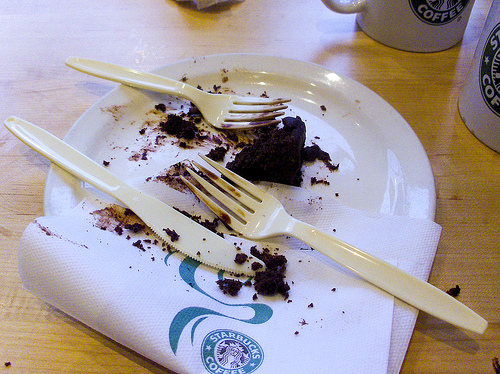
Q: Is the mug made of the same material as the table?
A: No, the mug is made of glass and the table is made of wood.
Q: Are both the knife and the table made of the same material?
A: No, the knife is made of plastic and the table is made of wood.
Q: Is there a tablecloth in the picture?
A: No, there are no tablecloths.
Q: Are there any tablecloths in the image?
A: No, there are no tablecloths.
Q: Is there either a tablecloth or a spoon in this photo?
A: No, there are no tablecloths or spoons.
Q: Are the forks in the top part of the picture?
A: Yes, the forks are in the top of the image.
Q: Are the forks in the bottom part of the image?
A: No, the forks are in the top of the image.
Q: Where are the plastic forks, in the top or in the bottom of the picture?
A: The forks are in the top of the image.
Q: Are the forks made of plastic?
A: Yes, the forks are made of plastic.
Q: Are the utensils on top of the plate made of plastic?
A: Yes, the forks are made of plastic.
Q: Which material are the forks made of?
A: The forks are made of plastic.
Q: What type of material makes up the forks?
A: The forks are made of plastic.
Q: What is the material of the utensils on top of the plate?
A: The forks are made of plastic.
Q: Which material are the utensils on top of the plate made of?
A: The forks are made of plastic.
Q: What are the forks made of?
A: The forks are made of plastic.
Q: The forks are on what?
A: The forks are on the plate.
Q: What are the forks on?
A: The forks are on the plate.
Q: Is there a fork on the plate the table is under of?
A: Yes, there are forks on the plate.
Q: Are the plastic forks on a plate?
A: Yes, the forks are on a plate.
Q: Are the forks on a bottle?
A: No, the forks are on a plate.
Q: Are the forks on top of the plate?
A: Yes, the forks are on top of the plate.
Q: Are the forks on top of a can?
A: No, the forks are on top of the plate.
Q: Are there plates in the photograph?
A: Yes, there is a plate.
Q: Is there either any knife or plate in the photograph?
A: Yes, there is a plate.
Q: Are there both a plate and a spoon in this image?
A: No, there is a plate but no spoons.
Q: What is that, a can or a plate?
A: That is a plate.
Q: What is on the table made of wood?
A: The plate is on the table.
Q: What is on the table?
A: The plate is on the table.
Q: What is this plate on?
A: The plate is on the table.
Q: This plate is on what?
A: The plate is on the table.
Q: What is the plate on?
A: The plate is on the table.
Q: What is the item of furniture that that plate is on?
A: The piece of furniture is a table.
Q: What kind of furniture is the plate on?
A: The plate is on the table.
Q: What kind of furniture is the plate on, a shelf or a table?
A: The plate is on a table.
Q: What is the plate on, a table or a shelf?
A: The plate is on a table.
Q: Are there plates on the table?
A: Yes, there is a plate on the table.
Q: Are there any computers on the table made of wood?
A: No, there is a plate on the table.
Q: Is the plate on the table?
A: Yes, the plate is on the table.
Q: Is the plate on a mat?
A: No, the plate is on the table.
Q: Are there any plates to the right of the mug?
A: No, the plate is to the left of the mug.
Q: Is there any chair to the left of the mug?
A: No, there is a plate to the left of the mug.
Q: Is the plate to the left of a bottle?
A: No, the plate is to the left of a mug.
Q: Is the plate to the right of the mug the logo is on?
A: No, the plate is to the left of the mug.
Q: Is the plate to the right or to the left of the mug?
A: The plate is to the left of the mug.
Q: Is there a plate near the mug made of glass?
A: Yes, there is a plate near the mug.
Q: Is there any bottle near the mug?
A: No, there is a plate near the mug.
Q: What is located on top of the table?
A: The plate is on top of the table.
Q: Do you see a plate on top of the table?
A: Yes, there is a plate on top of the table.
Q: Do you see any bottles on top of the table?
A: No, there is a plate on top of the table.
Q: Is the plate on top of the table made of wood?
A: Yes, the plate is on top of the table.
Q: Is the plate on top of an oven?
A: No, the plate is on top of the table.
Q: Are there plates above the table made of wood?
A: Yes, there is a plate above the table.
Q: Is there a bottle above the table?
A: No, there is a plate above the table.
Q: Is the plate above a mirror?
A: No, the plate is above a table.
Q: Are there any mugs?
A: Yes, there is a mug.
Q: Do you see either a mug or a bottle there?
A: Yes, there is a mug.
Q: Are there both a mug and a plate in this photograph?
A: Yes, there are both a mug and a plate.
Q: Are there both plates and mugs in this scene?
A: Yes, there are both a mug and a plate.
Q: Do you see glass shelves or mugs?
A: Yes, there is a glass mug.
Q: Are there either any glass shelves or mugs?
A: Yes, there is a glass mug.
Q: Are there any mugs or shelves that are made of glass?
A: Yes, the mug is made of glass.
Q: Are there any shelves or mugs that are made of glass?
A: Yes, the mug is made of glass.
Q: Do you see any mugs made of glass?
A: Yes, there is a mug that is made of glass.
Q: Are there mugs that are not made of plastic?
A: Yes, there is a mug that is made of glass.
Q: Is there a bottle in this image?
A: No, there are no bottles.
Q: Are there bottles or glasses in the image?
A: No, there are no bottles or glasses.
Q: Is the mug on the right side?
A: Yes, the mug is on the right of the image.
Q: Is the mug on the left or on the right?
A: The mug is on the right of the image.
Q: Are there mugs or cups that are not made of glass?
A: No, there is a mug but it is made of glass.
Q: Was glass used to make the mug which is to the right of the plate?
A: Yes, the mug is made of glass.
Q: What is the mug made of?
A: The mug is made of glass.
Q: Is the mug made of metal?
A: No, the mug is made of glass.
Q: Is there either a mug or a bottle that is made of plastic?
A: No, there is a mug but it is made of glass.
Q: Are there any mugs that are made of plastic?
A: No, there is a mug but it is made of glass.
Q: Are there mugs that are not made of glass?
A: No, there is a mug but it is made of glass.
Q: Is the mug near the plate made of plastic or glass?
A: The mug is made of glass.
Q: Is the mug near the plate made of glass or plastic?
A: The mug is made of glass.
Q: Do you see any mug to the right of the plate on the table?
A: Yes, there is a mug to the right of the plate.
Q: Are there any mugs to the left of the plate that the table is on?
A: No, the mug is to the right of the plate.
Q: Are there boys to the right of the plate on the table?
A: No, there is a mug to the right of the plate.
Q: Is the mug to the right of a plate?
A: Yes, the mug is to the right of a plate.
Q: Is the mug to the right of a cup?
A: No, the mug is to the right of a plate.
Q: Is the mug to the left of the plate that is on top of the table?
A: No, the mug is to the right of the plate.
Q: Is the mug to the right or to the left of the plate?
A: The mug is to the right of the plate.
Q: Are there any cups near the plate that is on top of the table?
A: No, there is a mug near the plate.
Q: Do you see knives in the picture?
A: Yes, there is a knife.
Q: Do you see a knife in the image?
A: Yes, there is a knife.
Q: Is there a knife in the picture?
A: Yes, there is a knife.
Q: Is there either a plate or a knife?
A: Yes, there is a knife.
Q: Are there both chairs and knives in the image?
A: No, there is a knife but no chairs.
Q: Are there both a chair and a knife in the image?
A: No, there is a knife but no chairs.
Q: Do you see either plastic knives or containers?
A: Yes, there is a plastic knife.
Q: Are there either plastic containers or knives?
A: Yes, there is a plastic knife.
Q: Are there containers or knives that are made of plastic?
A: Yes, the knife is made of plastic.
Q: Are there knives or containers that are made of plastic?
A: Yes, the knife is made of plastic.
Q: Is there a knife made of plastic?
A: Yes, there is a knife that is made of plastic.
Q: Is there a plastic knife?
A: Yes, there is a knife that is made of plastic.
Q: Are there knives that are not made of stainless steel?
A: Yes, there is a knife that is made of plastic.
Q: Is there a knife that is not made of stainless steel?
A: Yes, there is a knife that is made of plastic.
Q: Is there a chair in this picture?
A: No, there are no chairs.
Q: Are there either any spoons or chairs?
A: No, there are no chairs or spoons.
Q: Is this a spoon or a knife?
A: This is a knife.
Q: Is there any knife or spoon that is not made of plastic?
A: No, there is a knife but it is made of plastic.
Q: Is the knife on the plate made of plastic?
A: Yes, the knife is made of plastic.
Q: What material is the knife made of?
A: The knife is made of plastic.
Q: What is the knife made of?
A: The knife is made of plastic.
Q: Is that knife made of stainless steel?
A: No, the knife is made of plastic.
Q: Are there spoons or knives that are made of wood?
A: No, there is a knife but it is made of plastic.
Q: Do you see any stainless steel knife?
A: No, there is a knife but it is made of plastic.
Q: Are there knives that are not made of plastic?
A: No, there is a knife but it is made of plastic.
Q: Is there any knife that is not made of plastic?
A: No, there is a knife but it is made of plastic.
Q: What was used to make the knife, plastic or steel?
A: The knife is made of plastic.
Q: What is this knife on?
A: The knife is on the plate.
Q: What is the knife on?
A: The knife is on the plate.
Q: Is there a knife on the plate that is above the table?
A: Yes, there is a knife on the plate.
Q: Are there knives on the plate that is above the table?
A: Yes, there is a knife on the plate.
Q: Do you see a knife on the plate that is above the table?
A: Yes, there is a knife on the plate.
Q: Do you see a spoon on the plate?
A: No, there is a knife on the plate.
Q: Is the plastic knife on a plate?
A: Yes, the knife is on a plate.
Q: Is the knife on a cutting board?
A: No, the knife is on a plate.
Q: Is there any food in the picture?
A: Yes, there is food.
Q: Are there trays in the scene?
A: No, there are no trays.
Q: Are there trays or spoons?
A: No, there are no trays or spoons.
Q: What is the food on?
A: The food is on the plate.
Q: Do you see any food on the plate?
A: Yes, there is food on the plate.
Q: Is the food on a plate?
A: Yes, the food is on a plate.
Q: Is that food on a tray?
A: No, the food is on a plate.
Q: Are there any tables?
A: Yes, there is a table.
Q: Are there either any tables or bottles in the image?
A: Yes, there is a table.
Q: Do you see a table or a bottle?
A: Yes, there is a table.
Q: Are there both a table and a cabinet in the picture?
A: No, there is a table but no cabinets.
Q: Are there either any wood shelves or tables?
A: Yes, there is a wood table.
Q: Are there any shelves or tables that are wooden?
A: Yes, the table is wooden.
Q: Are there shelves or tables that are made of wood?
A: Yes, the table is made of wood.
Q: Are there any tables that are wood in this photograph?
A: Yes, there is a wood table.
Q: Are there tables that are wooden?
A: Yes, there is a table that is wooden.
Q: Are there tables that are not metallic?
A: Yes, there is a wooden table.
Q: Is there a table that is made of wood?
A: Yes, there is a table that is made of wood.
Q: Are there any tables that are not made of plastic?
A: Yes, there is a table that is made of wood.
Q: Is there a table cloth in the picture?
A: No, there are no tablecloths.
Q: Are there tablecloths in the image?
A: No, there are no tablecloths.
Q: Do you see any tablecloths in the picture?
A: No, there are no tablecloths.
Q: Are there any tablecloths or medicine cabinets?
A: No, there are no tablecloths or medicine cabinets.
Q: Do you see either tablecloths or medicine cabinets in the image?
A: No, there are no tablecloths or medicine cabinets.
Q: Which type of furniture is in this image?
A: The furniture is a table.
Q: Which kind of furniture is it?
A: The piece of furniture is a table.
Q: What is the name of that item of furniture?
A: This is a table.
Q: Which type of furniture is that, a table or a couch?
A: This is a table.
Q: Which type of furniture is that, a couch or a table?
A: This is a table.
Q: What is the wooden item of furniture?
A: The piece of furniture is a table.